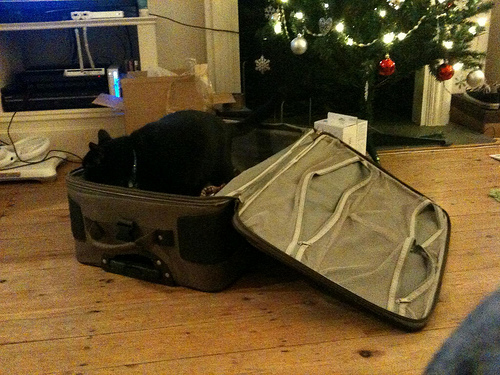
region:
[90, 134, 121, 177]
cat has black ears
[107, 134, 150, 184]
cat has dark collar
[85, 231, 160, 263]
black handle on luggage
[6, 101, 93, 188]
black cable on floor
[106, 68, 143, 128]
blue light on electronics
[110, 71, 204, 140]
brown box behind cat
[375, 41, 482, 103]
red and silver ornaments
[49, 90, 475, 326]
black cat in a suitcase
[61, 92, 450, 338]
suitcase is hanging open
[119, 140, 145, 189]
collar around the neck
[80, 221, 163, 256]
handle on the top of the suitcase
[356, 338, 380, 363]
dark brown spot on the wood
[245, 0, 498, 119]
bottom of a Christmas tree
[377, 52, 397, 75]
red ornament on the tree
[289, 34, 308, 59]
silver ornament on the tree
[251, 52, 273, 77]
snowflake ornament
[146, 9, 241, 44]
black wire running along the wall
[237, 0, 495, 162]
bottom section of an artificial Christmas tree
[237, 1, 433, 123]
section of fireplace behind tree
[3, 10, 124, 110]
entertainment devices near each other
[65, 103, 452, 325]
an open suitcase on its side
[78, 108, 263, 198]
black cat in suitcase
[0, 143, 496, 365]
floor appears to be genuine hardwood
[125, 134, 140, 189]
cat is wearing a collar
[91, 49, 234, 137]
open box near a wall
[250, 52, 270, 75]
star-shaped tree ornament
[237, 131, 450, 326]
open compartments on wall of suitcase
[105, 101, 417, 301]
black luggage is open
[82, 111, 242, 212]
cat inside black luggage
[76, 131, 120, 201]
cat has black ears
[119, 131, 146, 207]
cat has black collar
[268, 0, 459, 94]
Christmas tree behind cat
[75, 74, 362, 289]
luggage on brown floor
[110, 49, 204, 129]
brown box behind cat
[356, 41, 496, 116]
red and white ornaments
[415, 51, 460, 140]
small package under tree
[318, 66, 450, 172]
green base on tree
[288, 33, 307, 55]
An ornament on the tree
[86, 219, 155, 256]
A handle on the luggage case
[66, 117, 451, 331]
A luggage case on the ground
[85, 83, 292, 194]
A cat in the luggage case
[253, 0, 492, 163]
A Christmas Tree in the room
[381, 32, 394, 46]
A light on the tree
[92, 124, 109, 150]
The ears of the cat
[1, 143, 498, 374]
The floor beneath the luggage case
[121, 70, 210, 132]
An open box by the tree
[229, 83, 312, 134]
The tail of the cat